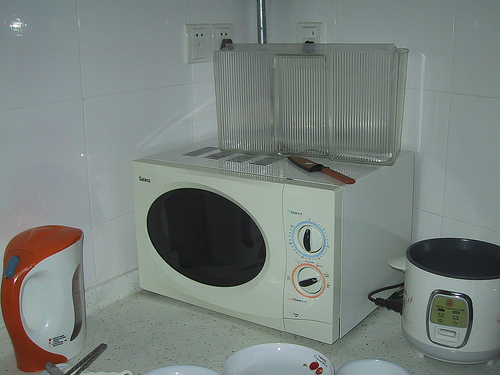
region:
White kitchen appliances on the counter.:
[128, 135, 498, 365]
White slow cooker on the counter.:
[366, 235, 496, 363]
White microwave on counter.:
[130, 135, 415, 346]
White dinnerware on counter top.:
[140, 340, 417, 371]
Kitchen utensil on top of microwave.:
[283, 152, 355, 187]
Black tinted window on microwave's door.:
[130, 158, 338, 345]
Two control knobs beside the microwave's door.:
[286, 217, 333, 309]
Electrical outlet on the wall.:
[168, 12, 321, 65]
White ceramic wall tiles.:
[10, 7, 181, 140]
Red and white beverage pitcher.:
[2, 225, 88, 370]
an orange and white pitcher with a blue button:
[0, 203, 99, 373]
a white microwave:
[127, 131, 416, 338]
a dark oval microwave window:
[142, 178, 269, 290]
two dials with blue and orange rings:
[284, 215, 333, 300]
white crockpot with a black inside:
[360, 233, 499, 364]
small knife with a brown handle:
[282, 147, 357, 188]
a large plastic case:
[210, 39, 411, 169]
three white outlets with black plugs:
[179, 15, 332, 66]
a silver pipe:
[255, 0, 272, 46]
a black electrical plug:
[362, 277, 409, 315]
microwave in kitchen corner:
[105, 36, 425, 347]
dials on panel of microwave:
[275, 185, 342, 340]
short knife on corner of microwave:
[280, 140, 360, 200]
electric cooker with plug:
[365, 225, 490, 360]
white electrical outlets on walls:
[176, 2, 328, 72]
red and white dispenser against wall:
[0, 200, 92, 366]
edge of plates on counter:
[135, 330, 402, 370]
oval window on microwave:
[135, 177, 285, 299]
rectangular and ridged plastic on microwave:
[201, 25, 411, 160]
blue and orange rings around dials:
[280, 210, 328, 305]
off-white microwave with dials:
[118, 151, 368, 336]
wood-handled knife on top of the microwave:
[271, 143, 370, 203]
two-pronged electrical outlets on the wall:
[175, 10, 362, 63]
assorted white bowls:
[162, 342, 446, 372]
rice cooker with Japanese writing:
[385, 205, 499, 363]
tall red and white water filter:
[2, 213, 85, 373]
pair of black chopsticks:
[48, 331, 103, 373]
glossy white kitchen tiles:
[13, 16, 131, 221]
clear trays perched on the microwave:
[217, 31, 407, 168]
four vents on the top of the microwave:
[182, 138, 279, 173]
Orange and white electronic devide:
[12, 210, 89, 367]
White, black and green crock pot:
[376, 204, 498, 363]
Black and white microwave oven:
[108, 123, 386, 348]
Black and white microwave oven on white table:
[104, 120, 401, 345]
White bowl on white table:
[208, 323, 325, 373]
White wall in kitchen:
[16, 27, 116, 197]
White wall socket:
[168, 14, 215, 62]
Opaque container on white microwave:
[210, 31, 418, 156]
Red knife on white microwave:
[290, 150, 362, 193]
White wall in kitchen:
[446, 30, 490, 209]